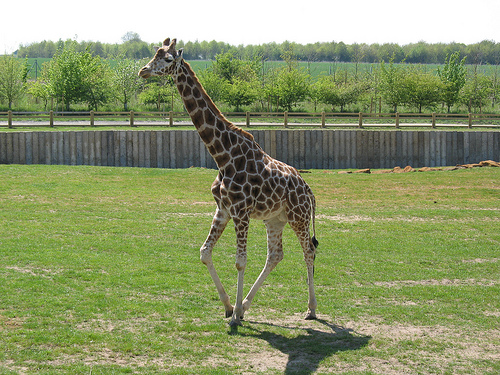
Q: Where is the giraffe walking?
A: On the grass.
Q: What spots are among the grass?
A: Brown dirt.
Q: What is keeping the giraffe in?
A: The fence.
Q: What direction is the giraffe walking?
A: Left.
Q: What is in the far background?
A: Trees.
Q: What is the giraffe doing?
A: Walking.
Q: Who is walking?
A: A giraffe.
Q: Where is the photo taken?
A: Zoo.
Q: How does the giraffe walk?
A: With its legs.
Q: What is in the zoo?
A: A giraffe.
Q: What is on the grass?
A: A giraffe.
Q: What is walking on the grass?
A: A giraffe.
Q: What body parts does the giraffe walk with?
A: Legs.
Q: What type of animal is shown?
A: A giraffe.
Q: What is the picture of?
A: An animal.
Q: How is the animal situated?
A: It's standing.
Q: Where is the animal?
A: In the grass.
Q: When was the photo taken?
A: During the day.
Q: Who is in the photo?
A: No one.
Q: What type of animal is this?
A: Giraffe.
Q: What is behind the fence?
A: Trees.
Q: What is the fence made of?
A: Wood.